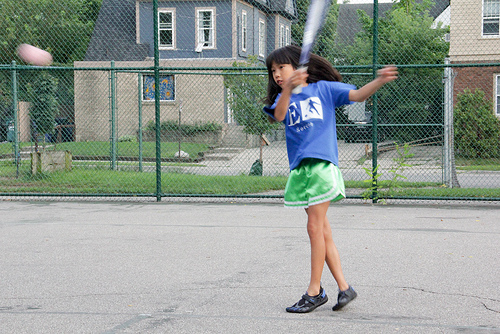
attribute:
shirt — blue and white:
[262, 89, 361, 166]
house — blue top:
[78, 2, 285, 145]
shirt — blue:
[255, 73, 363, 163]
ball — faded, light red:
[12, 35, 59, 75]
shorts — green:
[280, 159, 342, 210]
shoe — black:
[331, 284, 357, 311]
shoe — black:
[285, 283, 329, 312]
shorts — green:
[280, 158, 347, 209]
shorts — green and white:
[275, 160, 351, 211]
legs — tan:
[299, 193, 351, 293]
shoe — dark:
[284, 284, 332, 313]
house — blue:
[69, 3, 299, 145]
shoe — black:
[268, 280, 330, 315]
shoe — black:
[316, 268, 353, 308]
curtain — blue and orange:
[143, 75, 172, 98]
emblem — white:
[264, 101, 334, 128]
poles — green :
[128, 70, 208, 181]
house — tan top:
[444, 0, 498, 148]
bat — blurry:
[297, 1, 336, 88]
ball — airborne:
[16, 40, 59, 70]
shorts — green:
[283, 162, 347, 210]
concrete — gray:
[50, 222, 182, 332]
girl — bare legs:
[220, 45, 385, 331]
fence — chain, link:
[405, 72, 497, 192]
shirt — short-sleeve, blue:
[262, 80, 357, 166]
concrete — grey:
[1, 197, 498, 330]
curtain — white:
[195, 9, 212, 53]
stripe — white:
[326, 165, 346, 197]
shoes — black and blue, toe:
[292, 290, 354, 312]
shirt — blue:
[279, 86, 351, 161]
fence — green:
[2, 8, 497, 191]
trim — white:
[275, 163, 349, 209]